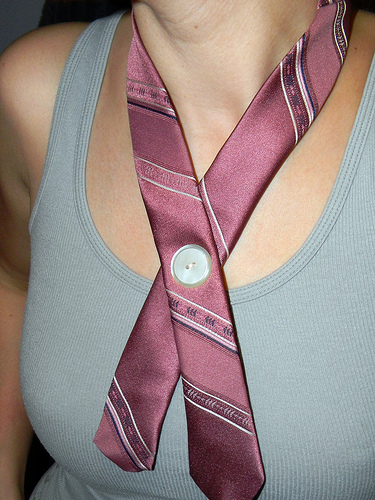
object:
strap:
[46, 7, 126, 174]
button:
[170, 242, 213, 289]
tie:
[90, 0, 367, 500]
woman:
[0, 0, 375, 500]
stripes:
[279, 60, 299, 146]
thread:
[188, 263, 194, 268]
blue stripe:
[105, 402, 143, 470]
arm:
[0, 22, 64, 500]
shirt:
[18, 7, 375, 500]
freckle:
[186, 18, 205, 37]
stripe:
[104, 371, 155, 475]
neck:
[128, 0, 358, 108]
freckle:
[192, 22, 200, 30]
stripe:
[180, 373, 255, 439]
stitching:
[72, 12, 375, 309]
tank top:
[14, 3, 373, 499]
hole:
[185, 264, 189, 269]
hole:
[192, 261, 196, 266]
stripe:
[125, 75, 166, 93]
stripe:
[125, 93, 173, 113]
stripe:
[125, 99, 176, 119]